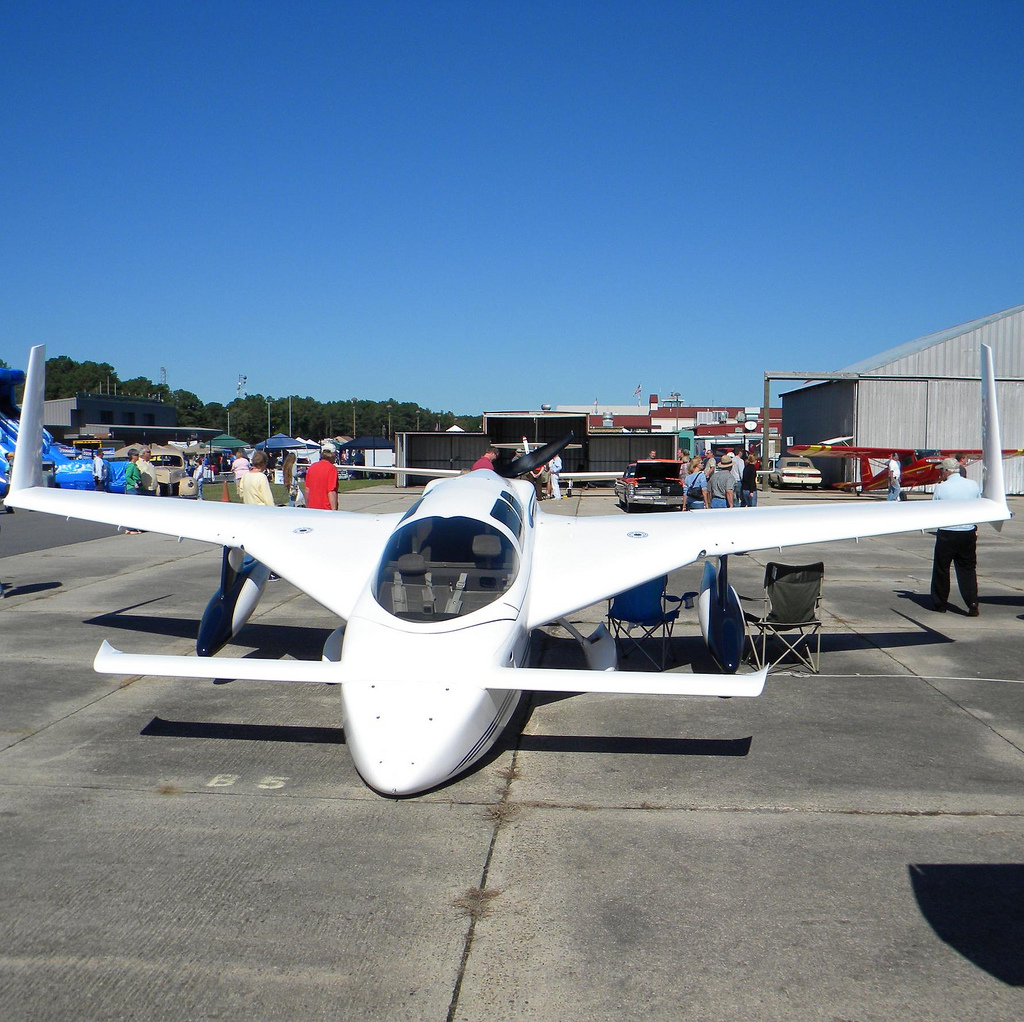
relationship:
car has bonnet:
[619, 456, 697, 511] [632, 462, 685, 499]